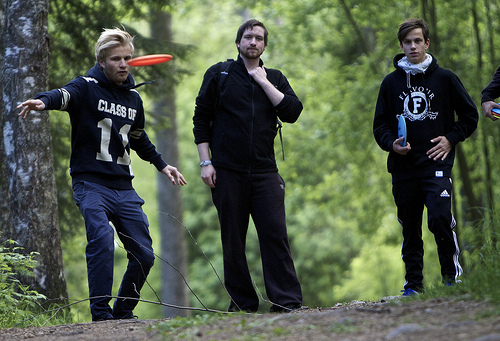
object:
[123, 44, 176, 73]
frisbe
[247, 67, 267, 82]
hand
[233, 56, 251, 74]
collar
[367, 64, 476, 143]
hoodie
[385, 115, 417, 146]
frisbee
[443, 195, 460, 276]
stripe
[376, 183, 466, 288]
pants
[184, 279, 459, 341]
hill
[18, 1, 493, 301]
forest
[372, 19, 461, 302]
players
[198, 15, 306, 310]
man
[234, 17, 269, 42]
hair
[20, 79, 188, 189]
sweatshirt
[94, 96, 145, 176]
class of 11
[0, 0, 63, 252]
tree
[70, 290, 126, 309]
branch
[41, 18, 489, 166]
background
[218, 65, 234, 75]
logo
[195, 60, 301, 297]
outfit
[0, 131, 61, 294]
trunk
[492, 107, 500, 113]
frisbees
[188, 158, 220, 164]
watch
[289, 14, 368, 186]
tree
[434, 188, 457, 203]
adidas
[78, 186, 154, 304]
jeans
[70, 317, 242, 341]
ground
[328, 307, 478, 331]
dirt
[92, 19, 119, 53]
hair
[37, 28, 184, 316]
men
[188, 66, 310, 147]
jacket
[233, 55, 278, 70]
neckline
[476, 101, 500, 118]
hand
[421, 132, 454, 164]
hand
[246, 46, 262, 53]
mouth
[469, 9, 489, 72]
woods